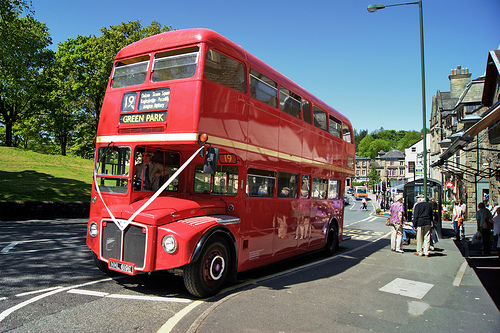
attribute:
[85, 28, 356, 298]
bus — red, double decker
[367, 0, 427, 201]
light — tall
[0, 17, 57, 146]
tree — tall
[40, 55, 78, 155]
tree — tall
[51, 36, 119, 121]
tree — tall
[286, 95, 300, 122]
man — standing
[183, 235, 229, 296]
wheel — black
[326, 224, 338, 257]
wheel — black